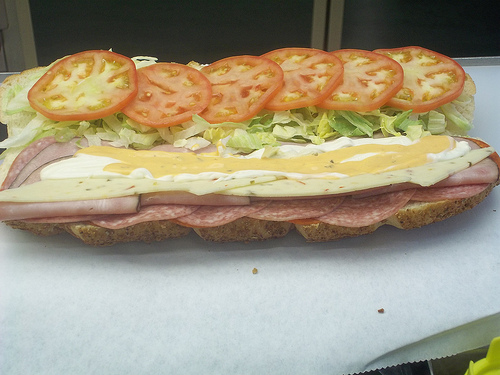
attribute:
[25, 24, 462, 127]
tomatoes — sliced, red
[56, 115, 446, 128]
lettuce — green, iceberg, shredded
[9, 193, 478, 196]
ham — red, folded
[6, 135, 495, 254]
bread — brown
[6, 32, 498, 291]
sandwich — submarine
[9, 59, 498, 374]
paper — white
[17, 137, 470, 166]
sauce — white, yellow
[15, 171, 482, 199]
cheese — sliced